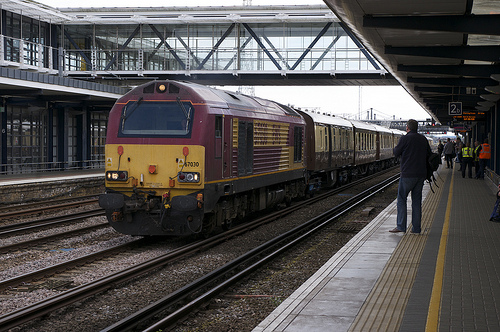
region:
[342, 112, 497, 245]
man waits at train platform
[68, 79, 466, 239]
red and yellow train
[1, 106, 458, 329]
brown gravel between the tracks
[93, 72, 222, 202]
numbers on the front of the train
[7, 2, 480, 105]
walkway connects both sides of the station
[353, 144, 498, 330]
yellow lines by the platform edge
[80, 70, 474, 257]
train is facing the camera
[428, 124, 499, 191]
men in uniforms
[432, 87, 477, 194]
sign indicates platform 2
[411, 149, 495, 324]
square gray pattern on the ground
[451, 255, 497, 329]
Gray bricks on a platform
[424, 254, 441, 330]
Yellow stripe on a train platform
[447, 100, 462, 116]
Black sign with 2b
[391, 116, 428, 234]
Man standing on a train platform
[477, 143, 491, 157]
Man wearing an orange jacket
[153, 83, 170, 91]
Headlight on a train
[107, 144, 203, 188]
Yellow panel on the front of a train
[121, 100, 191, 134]
Windshield on the front of a train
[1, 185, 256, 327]
Train tracks at a train station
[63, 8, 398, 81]
Bridge over a train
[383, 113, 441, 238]
man on the platform waiting for the train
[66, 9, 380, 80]
overhead walkway that crosses above the tracks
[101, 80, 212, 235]
front of train is red and yellow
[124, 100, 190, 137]
window so that the engineer can see ahead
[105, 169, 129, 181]
headlight on the left side of the engine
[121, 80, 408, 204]
this train is not a passenger train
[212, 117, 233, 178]
door on the side of the train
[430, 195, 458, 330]
yellow line on the platform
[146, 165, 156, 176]
red object in the center of the yellow on the front of the train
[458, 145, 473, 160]
person in neon yellow jacket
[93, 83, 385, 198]
The train is standing still.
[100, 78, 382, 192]
The train is red and yellow.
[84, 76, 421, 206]
The train carries people.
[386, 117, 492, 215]
The people are waiting for the train.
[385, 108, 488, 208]
The people are standing.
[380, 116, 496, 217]
The people are waiting for their train.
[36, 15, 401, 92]
The overpass is empty.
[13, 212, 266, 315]
The tracks are wet.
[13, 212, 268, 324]
There are multiple tracks.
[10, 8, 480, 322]
The train station has a few people.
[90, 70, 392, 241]
yellow and red train on tracks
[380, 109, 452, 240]
man standing on a train platform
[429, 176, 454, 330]
yellow safety line on a platform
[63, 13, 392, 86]
bridge connecting one side to the platform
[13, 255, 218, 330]
train tracks on the ground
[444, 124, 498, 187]
people waiting on a train platform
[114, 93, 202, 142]
front window of a train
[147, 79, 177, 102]
front light on a train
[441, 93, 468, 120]
number sign on train platform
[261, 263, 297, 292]
gravel next to the train tracks